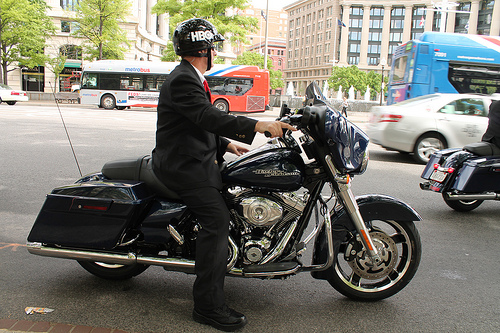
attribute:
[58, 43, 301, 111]
bus — one, moving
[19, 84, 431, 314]
bike — black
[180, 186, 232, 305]
pants — black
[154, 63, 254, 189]
jacket — black, suit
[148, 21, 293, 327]
man — one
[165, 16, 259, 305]
man — one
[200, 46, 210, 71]
strap — black , one, chin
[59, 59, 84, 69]
green awning — one, building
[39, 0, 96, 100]
building — one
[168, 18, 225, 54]
helmet — black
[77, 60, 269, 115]
bus — one, traveling, red, white, red and white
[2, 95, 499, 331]
street — one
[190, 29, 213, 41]
lettering — white, some, black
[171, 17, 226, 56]
helmet — one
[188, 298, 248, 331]
shoe — black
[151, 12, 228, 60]
helmet — black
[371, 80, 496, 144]
car — silver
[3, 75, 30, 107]
car — moving, white , one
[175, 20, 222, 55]
helmet — one, black, motorcycle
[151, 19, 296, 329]
rider — one, male, motorcycle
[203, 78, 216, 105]
necktie — one, red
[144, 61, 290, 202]
jacket — black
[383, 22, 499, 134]
bus — blue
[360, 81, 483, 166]
silver car — one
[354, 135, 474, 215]
street — one